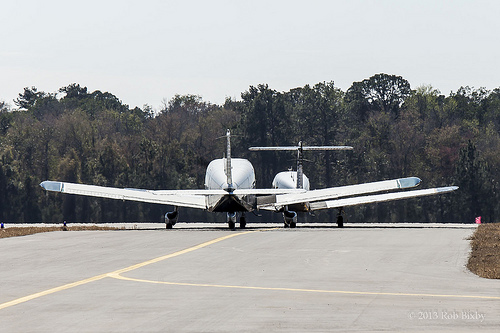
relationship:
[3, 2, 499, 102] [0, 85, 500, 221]
sky above trees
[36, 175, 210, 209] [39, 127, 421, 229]
wing on plane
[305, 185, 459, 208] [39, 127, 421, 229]
wing on plane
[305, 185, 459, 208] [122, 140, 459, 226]
wing on plane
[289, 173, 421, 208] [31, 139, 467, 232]
wing on plane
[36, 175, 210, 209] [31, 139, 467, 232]
wing on plane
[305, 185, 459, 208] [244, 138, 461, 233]
wing on plane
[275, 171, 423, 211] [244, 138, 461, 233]
wing on plane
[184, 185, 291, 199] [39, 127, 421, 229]
wing on plane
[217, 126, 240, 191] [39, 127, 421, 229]
tail of plane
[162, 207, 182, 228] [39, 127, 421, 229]
landing gear on plane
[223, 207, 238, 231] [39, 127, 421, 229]
gear on plane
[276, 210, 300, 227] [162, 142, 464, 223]
gear on plane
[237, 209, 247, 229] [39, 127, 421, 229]
landing gear on plane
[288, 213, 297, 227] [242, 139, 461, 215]
gear on plane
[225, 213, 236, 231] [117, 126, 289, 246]
gear on plane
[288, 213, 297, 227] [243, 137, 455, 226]
gear on plane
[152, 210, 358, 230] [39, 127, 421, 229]
landing gear on plane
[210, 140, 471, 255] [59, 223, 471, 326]
plane on runway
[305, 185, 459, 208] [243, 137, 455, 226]
wing on plane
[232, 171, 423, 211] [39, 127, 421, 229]
wing on plane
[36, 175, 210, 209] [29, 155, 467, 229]
wing on plane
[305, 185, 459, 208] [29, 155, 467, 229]
wing on plane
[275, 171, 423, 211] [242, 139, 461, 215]
wing on plane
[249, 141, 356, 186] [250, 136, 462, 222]
tail of plane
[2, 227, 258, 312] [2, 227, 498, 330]
line on runway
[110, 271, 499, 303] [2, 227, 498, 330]
line on runway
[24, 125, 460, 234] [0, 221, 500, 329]
airplanes on pavement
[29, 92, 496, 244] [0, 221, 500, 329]
trees at end of pavement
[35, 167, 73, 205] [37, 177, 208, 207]
tip of wing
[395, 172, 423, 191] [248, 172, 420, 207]
tip of wing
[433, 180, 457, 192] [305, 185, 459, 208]
tip of wing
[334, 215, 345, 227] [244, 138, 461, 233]
landing gear on plane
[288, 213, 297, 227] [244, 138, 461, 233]
gear on plane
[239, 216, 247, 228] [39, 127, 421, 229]
landing gear on plane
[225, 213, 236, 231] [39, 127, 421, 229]
gear on plane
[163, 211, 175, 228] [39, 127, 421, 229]
landing gear on plane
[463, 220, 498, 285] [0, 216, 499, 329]
grass on ground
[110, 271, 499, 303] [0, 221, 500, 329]
line on pavement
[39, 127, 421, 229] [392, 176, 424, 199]
plane with tip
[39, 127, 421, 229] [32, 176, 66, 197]
plane with tip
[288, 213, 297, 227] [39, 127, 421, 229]
gear on plane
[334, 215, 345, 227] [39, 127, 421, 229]
landing gear on plane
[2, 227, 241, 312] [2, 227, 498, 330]
line on runway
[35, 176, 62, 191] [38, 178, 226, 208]
tip of wing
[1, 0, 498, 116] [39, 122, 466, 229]
blue sky in front of planes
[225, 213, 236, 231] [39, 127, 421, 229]
gear of plane